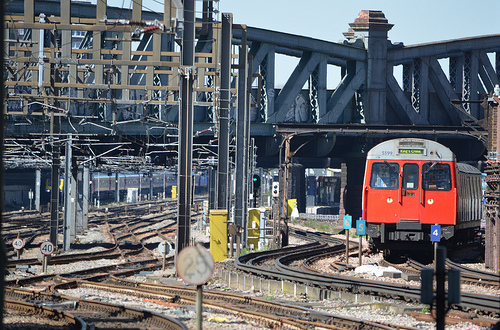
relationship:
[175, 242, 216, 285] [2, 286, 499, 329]
sign on ground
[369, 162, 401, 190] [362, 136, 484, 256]
window on train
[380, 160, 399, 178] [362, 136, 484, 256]
wiper on front of train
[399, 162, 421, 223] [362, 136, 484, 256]
door on front of train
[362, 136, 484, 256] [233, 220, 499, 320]
train on tracks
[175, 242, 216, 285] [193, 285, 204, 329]
sign on pole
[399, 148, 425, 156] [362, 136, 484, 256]
sign on train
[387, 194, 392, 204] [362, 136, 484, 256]
lights on front of train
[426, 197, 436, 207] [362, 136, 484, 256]
lights on front of train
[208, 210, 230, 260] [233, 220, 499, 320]
box right of tracks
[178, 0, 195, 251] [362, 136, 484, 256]
support above train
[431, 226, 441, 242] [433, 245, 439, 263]
number on pole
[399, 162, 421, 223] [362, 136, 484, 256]
door on train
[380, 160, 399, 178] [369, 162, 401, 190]
wiper on window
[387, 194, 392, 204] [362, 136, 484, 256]
lights on train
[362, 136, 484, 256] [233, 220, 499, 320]
train atop tracks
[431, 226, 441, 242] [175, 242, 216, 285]
number on sign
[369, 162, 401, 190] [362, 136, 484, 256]
window on front of train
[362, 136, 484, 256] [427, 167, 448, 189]
train being driven